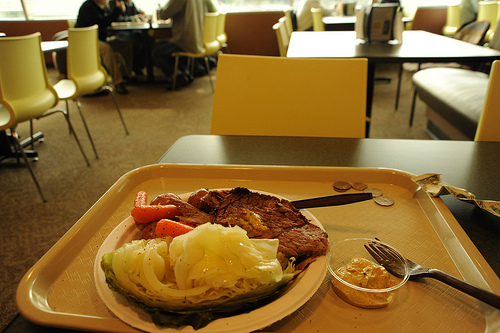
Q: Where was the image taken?
A: It was taken at the restaurant.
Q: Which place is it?
A: It is a restaurant.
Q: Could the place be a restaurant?
A: Yes, it is a restaurant.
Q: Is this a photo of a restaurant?
A: Yes, it is showing a restaurant.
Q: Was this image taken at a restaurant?
A: Yes, it was taken in a restaurant.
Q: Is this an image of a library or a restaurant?
A: It is showing a restaurant.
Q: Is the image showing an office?
A: No, the picture is showing a restaurant.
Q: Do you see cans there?
A: No, there are no cans.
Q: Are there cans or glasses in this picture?
A: No, there are no cans or glasses.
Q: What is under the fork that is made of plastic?
A: The tray is under the fork.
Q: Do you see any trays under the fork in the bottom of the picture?
A: Yes, there is a tray under the fork.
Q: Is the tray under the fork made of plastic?
A: Yes, the tray is under the fork.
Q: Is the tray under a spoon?
A: No, the tray is under the fork.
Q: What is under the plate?
A: The tray is under the plate.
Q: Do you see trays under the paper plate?
A: Yes, there is a tray under the plate.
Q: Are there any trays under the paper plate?
A: Yes, there is a tray under the plate.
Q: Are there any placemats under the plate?
A: No, there is a tray under the plate.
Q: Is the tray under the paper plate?
A: Yes, the tray is under the plate.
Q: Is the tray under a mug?
A: No, the tray is under the plate.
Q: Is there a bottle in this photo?
A: No, there are no bottles.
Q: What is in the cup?
A: The sauce is in the cup.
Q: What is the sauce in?
A: The sauce is in the cup.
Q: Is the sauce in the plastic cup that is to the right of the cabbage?
A: Yes, the sauce is in the cup.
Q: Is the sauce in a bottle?
A: No, the sauce is in the cup.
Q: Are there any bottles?
A: No, there are no bottles.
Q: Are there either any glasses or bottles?
A: No, there are no bottles or glasses.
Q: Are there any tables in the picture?
A: Yes, there is a table.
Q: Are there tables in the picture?
A: Yes, there is a table.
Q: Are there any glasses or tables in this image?
A: Yes, there is a table.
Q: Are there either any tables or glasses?
A: Yes, there is a table.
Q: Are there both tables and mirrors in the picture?
A: No, there is a table but no mirrors.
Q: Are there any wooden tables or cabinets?
A: Yes, there is a wood table.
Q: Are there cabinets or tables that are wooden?
A: Yes, the table is wooden.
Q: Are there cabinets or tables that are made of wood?
A: Yes, the table is made of wood.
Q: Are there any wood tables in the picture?
A: Yes, there is a wood table.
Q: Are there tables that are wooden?
A: Yes, there is a table that is wooden.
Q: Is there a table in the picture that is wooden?
A: Yes, there is a table that is wooden.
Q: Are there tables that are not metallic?
A: Yes, there is a wooden table.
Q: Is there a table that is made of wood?
A: Yes, there is a table that is made of wood.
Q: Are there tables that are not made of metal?
A: Yes, there is a table that is made of wood.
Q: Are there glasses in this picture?
A: No, there are no glasses.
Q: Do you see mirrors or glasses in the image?
A: No, there are no glasses or mirrors.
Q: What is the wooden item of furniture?
A: The piece of furniture is a table.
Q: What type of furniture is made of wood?
A: The furniture is a table.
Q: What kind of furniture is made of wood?
A: The furniture is a table.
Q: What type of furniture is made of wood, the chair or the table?
A: The table is made of wood.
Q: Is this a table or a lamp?
A: This is a table.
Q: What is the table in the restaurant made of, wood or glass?
A: The table is made of wood.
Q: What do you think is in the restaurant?
A: The table is in the restaurant.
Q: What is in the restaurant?
A: The table is in the restaurant.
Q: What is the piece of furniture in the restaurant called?
A: The piece of furniture is a table.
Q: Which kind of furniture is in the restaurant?
A: The piece of furniture is a table.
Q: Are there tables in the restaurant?
A: Yes, there is a table in the restaurant.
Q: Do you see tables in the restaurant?
A: Yes, there is a table in the restaurant.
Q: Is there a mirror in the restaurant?
A: No, there is a table in the restaurant.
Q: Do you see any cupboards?
A: No, there are no cupboards.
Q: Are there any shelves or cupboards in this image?
A: No, there are no cupboards or shelves.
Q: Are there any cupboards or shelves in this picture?
A: No, there are no cupboards or shelves.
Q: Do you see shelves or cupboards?
A: No, there are no cupboards or shelves.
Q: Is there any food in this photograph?
A: Yes, there is food.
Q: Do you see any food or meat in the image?
A: Yes, there is food.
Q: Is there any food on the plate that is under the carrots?
A: Yes, there is food on the plate.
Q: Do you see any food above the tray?
A: Yes, there is food above the tray.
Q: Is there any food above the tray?
A: Yes, there is food above the tray.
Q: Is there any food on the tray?
A: Yes, there is food on the tray.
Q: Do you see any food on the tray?
A: Yes, there is food on the tray.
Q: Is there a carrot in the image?
A: Yes, there are carrots.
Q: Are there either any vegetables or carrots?
A: Yes, there are carrots.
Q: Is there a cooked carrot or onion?
A: Yes, there are cooked carrots.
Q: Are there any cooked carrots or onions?
A: Yes, there are cooked carrots.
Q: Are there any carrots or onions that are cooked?
A: Yes, the carrots are cooked.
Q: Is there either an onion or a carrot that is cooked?
A: Yes, the carrots are cooked.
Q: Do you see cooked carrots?
A: Yes, there are cooked carrots.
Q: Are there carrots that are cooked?
A: Yes, there are carrots that are cooked.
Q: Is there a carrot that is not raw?
A: Yes, there are cooked carrots.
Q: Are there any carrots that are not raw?
A: Yes, there are cooked carrots.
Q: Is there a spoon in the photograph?
A: No, there are no spoons.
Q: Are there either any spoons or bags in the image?
A: No, there are no spoons or bags.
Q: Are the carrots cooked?
A: Yes, the carrots are cooked.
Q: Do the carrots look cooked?
A: Yes, the carrots are cooked.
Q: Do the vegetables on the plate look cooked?
A: Yes, the carrots are cooked.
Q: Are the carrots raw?
A: No, the carrots are cooked.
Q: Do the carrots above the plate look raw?
A: No, the carrots are cooked.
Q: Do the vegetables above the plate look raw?
A: No, the carrots are cooked.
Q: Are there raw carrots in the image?
A: No, there are carrots but they are cooked.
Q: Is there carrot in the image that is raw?
A: No, there are carrots but they are cooked.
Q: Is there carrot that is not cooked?
A: No, there are carrots but they are cooked.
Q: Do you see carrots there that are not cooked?
A: No, there are carrots but they are cooked.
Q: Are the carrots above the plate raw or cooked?
A: The carrots are cooked.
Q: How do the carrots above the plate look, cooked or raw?
A: The carrots are cooked.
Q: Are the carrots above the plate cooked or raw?
A: The carrots are cooked.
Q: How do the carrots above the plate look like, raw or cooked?
A: The carrots are cooked.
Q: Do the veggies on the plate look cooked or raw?
A: The carrots are cooked.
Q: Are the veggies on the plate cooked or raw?
A: The carrots are cooked.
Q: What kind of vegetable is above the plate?
A: The vegetables are carrots.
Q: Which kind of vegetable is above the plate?
A: The vegetables are carrots.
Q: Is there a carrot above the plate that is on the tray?
A: Yes, there are carrots above the plate.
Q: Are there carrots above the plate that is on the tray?
A: Yes, there are carrots above the plate.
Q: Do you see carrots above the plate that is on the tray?
A: Yes, there are carrots above the plate.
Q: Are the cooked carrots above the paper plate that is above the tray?
A: Yes, the carrots are above the plate.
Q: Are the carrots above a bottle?
A: No, the carrots are above the plate.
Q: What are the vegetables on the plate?
A: The vegetables are carrots.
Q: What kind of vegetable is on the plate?
A: The vegetables are carrots.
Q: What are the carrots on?
A: The carrots are on the plate.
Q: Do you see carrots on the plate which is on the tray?
A: Yes, there are carrots on the plate.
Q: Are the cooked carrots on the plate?
A: Yes, the carrots are on the plate.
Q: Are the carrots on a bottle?
A: No, the carrots are on the plate.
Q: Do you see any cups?
A: Yes, there is a cup.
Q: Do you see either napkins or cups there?
A: Yes, there is a cup.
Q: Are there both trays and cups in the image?
A: Yes, there are both a cup and a tray.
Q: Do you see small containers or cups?
A: Yes, there is a small cup.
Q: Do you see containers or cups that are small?
A: Yes, the cup is small.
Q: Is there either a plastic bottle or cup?
A: Yes, there is a plastic cup.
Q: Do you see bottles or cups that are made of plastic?
A: Yes, the cup is made of plastic.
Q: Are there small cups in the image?
A: Yes, there is a small cup.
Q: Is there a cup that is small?
A: Yes, there is a cup that is small.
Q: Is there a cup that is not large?
A: Yes, there is a small cup.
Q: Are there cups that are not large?
A: Yes, there is a small cup.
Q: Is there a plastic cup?
A: Yes, there is a cup that is made of plastic.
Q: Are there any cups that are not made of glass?
A: Yes, there is a cup that is made of plastic.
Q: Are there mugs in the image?
A: No, there are no mugs.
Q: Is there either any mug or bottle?
A: No, there are no mugs or bottles.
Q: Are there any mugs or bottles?
A: No, there are no mugs or bottles.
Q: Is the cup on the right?
A: Yes, the cup is on the right of the image.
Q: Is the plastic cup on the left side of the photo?
A: No, the cup is on the right of the image.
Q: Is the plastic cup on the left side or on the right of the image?
A: The cup is on the right of the image.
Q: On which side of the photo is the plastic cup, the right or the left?
A: The cup is on the right of the image.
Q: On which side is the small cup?
A: The cup is on the right of the image.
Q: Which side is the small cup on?
A: The cup is on the right of the image.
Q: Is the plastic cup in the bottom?
A: Yes, the cup is in the bottom of the image.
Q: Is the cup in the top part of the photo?
A: No, the cup is in the bottom of the image.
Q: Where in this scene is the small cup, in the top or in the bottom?
A: The cup is in the bottom of the image.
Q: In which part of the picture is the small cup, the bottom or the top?
A: The cup is in the bottom of the image.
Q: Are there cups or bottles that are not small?
A: No, there is a cup but it is small.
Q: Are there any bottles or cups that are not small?
A: No, there is a cup but it is small.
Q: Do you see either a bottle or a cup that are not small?
A: No, there is a cup but it is small.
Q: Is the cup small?
A: Yes, the cup is small.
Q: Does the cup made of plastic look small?
A: Yes, the cup is small.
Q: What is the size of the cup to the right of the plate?
A: The cup is small.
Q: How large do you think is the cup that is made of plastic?
A: The cup is small.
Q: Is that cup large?
A: No, the cup is small.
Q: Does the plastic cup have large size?
A: No, the cup is small.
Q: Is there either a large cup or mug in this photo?
A: No, there is a cup but it is small.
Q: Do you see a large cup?
A: No, there is a cup but it is small.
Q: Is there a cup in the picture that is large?
A: No, there is a cup but it is small.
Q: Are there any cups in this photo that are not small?
A: No, there is a cup but it is small.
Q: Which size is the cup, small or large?
A: The cup is small.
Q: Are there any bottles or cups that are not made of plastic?
A: No, there is a cup but it is made of plastic.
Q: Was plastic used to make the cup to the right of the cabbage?
A: Yes, the cup is made of plastic.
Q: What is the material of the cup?
A: The cup is made of plastic.